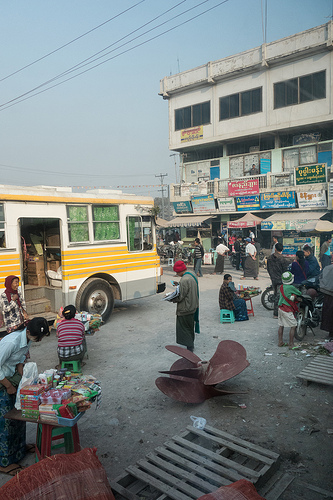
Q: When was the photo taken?
A: Daytime.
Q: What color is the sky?
A: Blue and white.